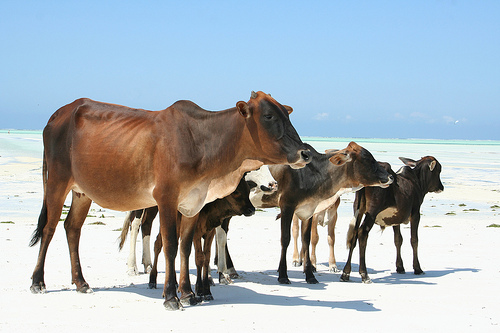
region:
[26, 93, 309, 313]
a brown cow with a black face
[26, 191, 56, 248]
the black tail of the brown cow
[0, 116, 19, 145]
a person in the distance of the beach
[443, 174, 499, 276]
plants growing to the right of the cows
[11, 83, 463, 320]
several cows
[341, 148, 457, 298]
a young black cow facing away from the camera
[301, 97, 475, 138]
sparse clouds in the distance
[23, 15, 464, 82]
blue skies behind the cows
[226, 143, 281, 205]
the partially hidden white face of a cow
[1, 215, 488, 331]
a white beach with cow shadows being cast on it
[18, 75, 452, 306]
Cows on a field cover with snow.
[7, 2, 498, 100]
Sky is blue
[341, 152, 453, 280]
Calf facing to the right.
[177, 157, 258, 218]
Chest of cow id white.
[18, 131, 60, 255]
Long tail of cow.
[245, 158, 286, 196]
Head of calf is white.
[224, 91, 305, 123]
Ears on cow on side of head.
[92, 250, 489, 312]
Shadows of cows on ground.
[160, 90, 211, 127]
Bump on back of cow.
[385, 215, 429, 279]
Front legs of calf.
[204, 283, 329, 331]
Ground covered in snow.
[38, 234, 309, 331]
Snow on ground is white.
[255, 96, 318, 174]
Cow has black face.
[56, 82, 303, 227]
Large cow is standing in front of other cows.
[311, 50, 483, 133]
Sky is blue in color.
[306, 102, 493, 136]
Mountains in the background.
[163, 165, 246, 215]
Cow has white chest.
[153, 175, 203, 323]
Cow's legs are black.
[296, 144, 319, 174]
Cow has black nose.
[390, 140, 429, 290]
Cow is facing the other way.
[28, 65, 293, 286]
a mama cow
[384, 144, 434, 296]
a herd of cow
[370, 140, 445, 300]
a baby cow on a field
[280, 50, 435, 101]
nice clear skies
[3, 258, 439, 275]
the legs of many cows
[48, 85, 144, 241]
a big cows butt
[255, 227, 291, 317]
what looks like sand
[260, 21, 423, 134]
a few clouds in the sky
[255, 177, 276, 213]
a little cows face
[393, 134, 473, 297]
a cow looking into the horizon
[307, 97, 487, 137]
a few clouds in the distance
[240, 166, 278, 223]
the partially hidden white face of a cow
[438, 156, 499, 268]
sparse green plants growing to the right of the cows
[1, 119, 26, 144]
a person in the distance on the beach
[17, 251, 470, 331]
white beach sands with cow shadows being cast on them